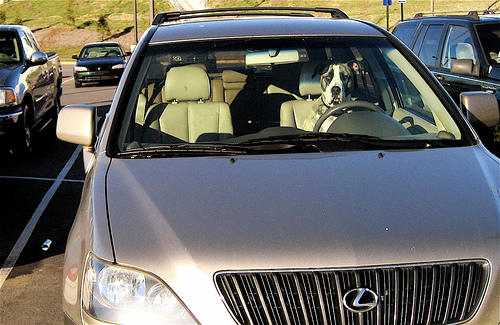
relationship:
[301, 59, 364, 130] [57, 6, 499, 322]
dog in vehicle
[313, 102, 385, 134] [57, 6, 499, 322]
steering wheel of vehicle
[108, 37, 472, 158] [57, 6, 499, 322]
windshield of vehicle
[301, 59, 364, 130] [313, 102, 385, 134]
dog behind steering wheel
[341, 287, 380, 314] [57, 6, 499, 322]
lexus logo on vehicle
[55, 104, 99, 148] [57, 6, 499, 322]
side view mirror of vehicle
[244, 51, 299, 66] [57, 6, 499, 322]
rear view mirror of vehicle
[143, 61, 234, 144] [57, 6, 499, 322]
passenger seat of vehicle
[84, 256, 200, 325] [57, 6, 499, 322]
headlight of vehicle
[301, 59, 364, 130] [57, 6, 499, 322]
dog inside vehicle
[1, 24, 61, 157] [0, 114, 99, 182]
truck in parking space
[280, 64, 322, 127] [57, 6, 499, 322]
drivers seat in vehicle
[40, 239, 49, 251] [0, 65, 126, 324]
can on ground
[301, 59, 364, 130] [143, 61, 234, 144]
dog in passenger seat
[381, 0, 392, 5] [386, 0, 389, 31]
sign on post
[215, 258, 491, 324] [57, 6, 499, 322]
front grille of vehicle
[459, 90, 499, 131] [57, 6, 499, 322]
side view mirror of vehicle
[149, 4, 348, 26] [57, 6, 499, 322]
luggage rack on top of vehicle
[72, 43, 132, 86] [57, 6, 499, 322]
car behind vehicle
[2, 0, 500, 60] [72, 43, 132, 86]
grass behind car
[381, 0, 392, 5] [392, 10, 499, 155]
sign behind suv